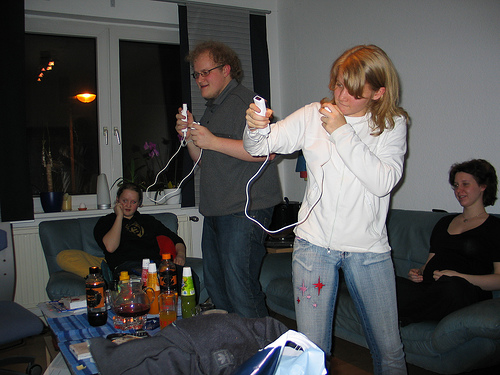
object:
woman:
[241, 42, 410, 373]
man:
[175, 41, 282, 318]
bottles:
[160, 282, 178, 327]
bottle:
[179, 266, 197, 319]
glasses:
[188, 61, 225, 79]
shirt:
[242, 101, 408, 254]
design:
[296, 276, 326, 308]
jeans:
[291, 234, 408, 374]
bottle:
[145, 262, 161, 315]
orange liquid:
[145, 290, 162, 313]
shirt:
[198, 76, 284, 216]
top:
[422, 214, 499, 281]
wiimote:
[252, 95, 270, 136]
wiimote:
[180, 102, 188, 132]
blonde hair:
[320, 44, 413, 137]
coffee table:
[40, 289, 228, 374]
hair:
[447, 158, 499, 206]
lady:
[397, 159, 499, 326]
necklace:
[459, 210, 487, 221]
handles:
[114, 128, 121, 145]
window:
[25, 10, 199, 214]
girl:
[93, 182, 203, 307]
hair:
[185, 39, 246, 83]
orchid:
[142, 141, 160, 158]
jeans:
[201, 203, 277, 318]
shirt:
[93, 210, 186, 271]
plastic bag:
[230, 330, 330, 375]